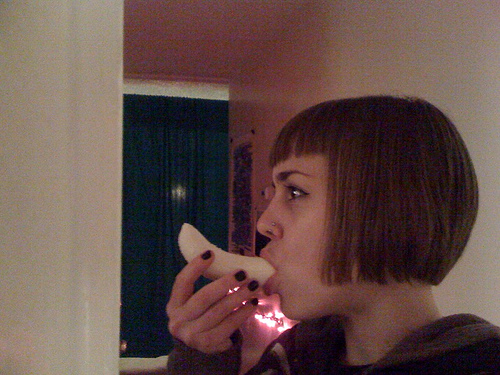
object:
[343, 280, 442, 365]
neck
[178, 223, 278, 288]
banana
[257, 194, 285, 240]
nose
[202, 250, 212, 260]
fingernail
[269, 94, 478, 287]
bob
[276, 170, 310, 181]
eyebrow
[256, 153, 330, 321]
face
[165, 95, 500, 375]
woman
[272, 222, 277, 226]
piercing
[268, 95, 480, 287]
hair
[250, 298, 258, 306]
nail polish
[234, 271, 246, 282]
nail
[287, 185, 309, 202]
eye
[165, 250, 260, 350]
hand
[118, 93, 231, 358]
curtain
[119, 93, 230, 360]
doorway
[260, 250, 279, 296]
lips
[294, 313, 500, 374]
hood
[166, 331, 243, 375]
long sleeve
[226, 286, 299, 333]
light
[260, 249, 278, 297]
woman's mouth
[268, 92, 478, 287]
bobcut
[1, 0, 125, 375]
wall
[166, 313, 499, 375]
sweatshirt